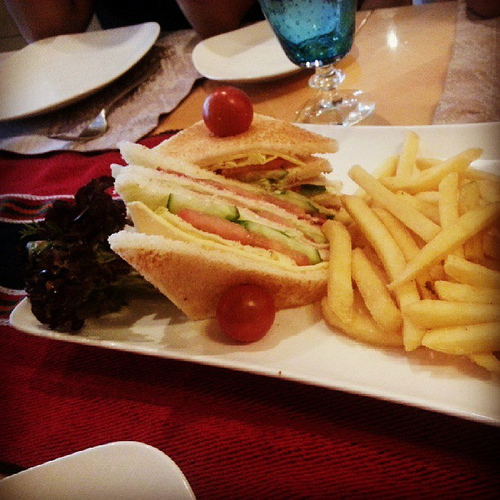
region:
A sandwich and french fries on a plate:
[108, 83, 498, 403]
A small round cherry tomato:
[200, 83, 258, 139]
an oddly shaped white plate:
[2, 19, 160, 123]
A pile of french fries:
[325, 130, 498, 365]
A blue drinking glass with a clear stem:
[255, 0, 383, 125]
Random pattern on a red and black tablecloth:
[202, 402, 411, 499]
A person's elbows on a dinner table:
[10, 0, 249, 49]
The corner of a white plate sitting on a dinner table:
[2, 420, 199, 498]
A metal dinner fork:
[35, 55, 190, 146]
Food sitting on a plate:
[12, 83, 498, 420]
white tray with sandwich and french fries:
[21, 102, 486, 392]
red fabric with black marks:
[0, 330, 495, 495]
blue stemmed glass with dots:
[260, 0, 376, 120]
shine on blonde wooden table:
[150, 5, 455, 125]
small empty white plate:
[192, 21, 293, 81]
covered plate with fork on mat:
[5, 20, 191, 150]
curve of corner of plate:
[5, 436, 190, 491]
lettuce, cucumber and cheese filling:
[135, 167, 310, 264]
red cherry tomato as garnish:
[211, 285, 272, 341]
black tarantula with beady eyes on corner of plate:
[23, 177, 145, 332]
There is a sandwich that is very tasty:
[184, 166, 252, 284]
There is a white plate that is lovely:
[326, 358, 344, 400]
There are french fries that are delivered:
[390, 212, 425, 302]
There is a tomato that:
[214, 290, 268, 358]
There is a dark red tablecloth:
[264, 430, 286, 475]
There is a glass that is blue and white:
[275, 5, 399, 115]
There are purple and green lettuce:
[68, 210, 116, 334]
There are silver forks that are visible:
[93, 72, 144, 187]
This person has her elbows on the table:
[195, 3, 225, 33]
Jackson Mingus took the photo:
[176, 189, 381, 459]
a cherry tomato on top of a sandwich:
[190, 82, 255, 149]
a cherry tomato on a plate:
[176, 273, 289, 390]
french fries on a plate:
[358, 115, 481, 420]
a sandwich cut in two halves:
[107, 73, 309, 335]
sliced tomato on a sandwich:
[157, 222, 312, 256]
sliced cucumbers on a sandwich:
[148, 194, 297, 226]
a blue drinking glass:
[279, 1, 379, 125]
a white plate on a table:
[146, 322, 456, 394]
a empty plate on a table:
[0, 14, 159, 128]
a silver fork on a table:
[58, 52, 163, 167]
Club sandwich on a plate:
[108, 83, 341, 344]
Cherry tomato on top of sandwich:
[200, 88, 254, 135]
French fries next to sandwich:
[318, 130, 498, 372]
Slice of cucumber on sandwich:
[165, 189, 241, 220]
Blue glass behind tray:
[264, 0, 379, 124]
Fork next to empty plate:
[45, 55, 162, 142]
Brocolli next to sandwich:
[19, 170, 124, 339]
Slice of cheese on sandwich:
[124, 198, 262, 257]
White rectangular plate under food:
[9, 115, 498, 425]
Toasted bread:
[107, 231, 339, 319]